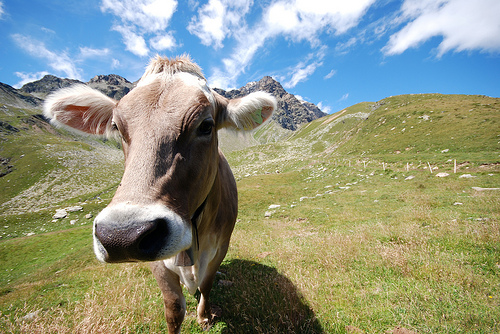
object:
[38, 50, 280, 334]
cow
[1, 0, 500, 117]
sky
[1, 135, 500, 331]
grass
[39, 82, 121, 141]
ears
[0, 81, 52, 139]
mountains